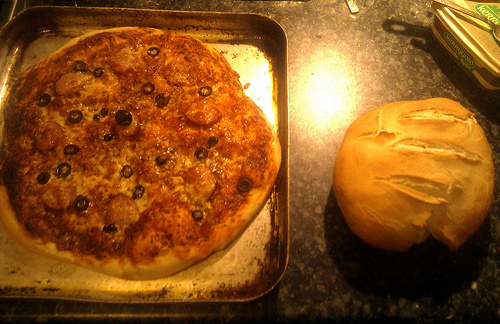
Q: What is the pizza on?
A: A pan.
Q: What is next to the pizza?
A: Bread.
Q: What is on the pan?
A: A pizza.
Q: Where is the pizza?
A: At the left of the photo.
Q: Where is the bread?
A: At the right of the photo.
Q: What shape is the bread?
A: Round.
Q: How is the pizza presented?
A: In a pan.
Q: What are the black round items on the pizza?
A: Olives.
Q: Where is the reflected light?
A: Between the pizza and bread.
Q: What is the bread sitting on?
A: The counter.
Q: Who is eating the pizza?
A: Nobody is eating.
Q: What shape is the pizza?
A: Round.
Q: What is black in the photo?
A: The countertop.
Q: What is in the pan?
A: Pizza.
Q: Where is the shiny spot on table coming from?
A: A light.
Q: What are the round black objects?
A: Black olives.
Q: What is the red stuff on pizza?
A: Tomato sauce.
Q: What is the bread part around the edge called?
A: Crust.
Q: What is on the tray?
A: A pizza.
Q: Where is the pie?
A: On the tray.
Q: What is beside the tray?
A: A bread.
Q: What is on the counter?
A: Tray and bread.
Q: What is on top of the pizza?
A: Cheese and olives.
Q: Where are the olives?
A: On the pizza.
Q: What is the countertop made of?
A: Marble.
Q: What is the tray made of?
A: Stainless steel.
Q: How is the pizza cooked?
A: It is baked.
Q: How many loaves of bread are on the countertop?
A: 1.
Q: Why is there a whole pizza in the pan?
A: Freshly baked.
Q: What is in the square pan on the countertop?
A: Pizza.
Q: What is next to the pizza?
A: Bread.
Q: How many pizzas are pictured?
A: One.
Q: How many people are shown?
A: None.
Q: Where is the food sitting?
A: Countertop.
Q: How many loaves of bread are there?
A: One.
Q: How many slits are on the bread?
A: Three.